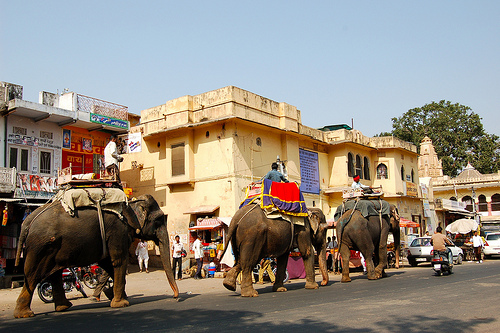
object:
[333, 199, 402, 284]
elephant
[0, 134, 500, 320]
parade.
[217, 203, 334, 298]
elephant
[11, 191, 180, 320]
elephants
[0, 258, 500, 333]
street.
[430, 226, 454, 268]
man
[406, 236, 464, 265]
car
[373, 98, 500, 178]
tree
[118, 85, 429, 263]
building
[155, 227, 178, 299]
trunk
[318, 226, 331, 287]
trunk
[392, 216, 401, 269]
trunk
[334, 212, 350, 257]
tail.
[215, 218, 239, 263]
tail.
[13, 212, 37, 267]
tail.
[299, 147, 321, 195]
sign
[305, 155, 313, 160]
writing.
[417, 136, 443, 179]
tower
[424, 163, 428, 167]
stone.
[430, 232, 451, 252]
shirt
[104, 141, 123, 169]
shirt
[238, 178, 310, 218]
blanket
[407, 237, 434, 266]
back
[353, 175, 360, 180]
headband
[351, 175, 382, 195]
man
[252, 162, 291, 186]
man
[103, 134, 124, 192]
man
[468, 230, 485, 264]
man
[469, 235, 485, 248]
shirt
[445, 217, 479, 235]
umbrella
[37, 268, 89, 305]
motorcycle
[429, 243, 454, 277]
moped.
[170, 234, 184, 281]
man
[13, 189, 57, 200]
sign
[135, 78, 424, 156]
roof.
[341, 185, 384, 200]
saddle.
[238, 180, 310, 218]
saddle.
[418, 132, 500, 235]
building.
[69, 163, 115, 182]
fence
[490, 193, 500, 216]
windows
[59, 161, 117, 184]
balcony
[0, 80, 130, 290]
building.